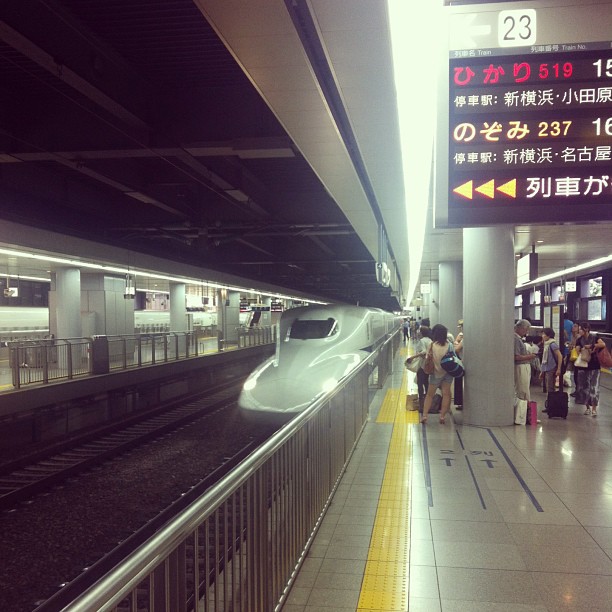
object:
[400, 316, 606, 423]
people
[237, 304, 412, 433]
train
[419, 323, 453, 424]
person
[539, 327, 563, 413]
person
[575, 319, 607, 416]
person